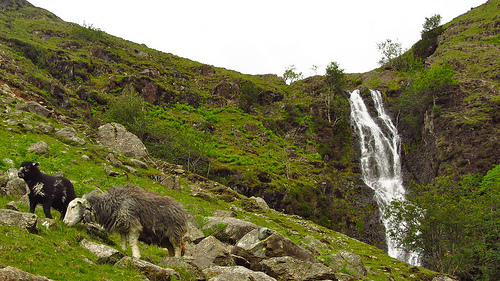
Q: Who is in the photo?
A: No people.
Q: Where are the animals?
A: On the grass.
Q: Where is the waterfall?
A: Right.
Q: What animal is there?
A: Sheep.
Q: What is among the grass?
A: Rocks.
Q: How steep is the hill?
A: Very steep.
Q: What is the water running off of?
A: Cliff.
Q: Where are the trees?
A: Scattered.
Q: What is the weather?
A: Mild.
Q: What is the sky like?
A: Overcast.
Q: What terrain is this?
A: Hillside.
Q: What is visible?
A: Waterfalls.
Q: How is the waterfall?
A: High.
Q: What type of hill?
A: Rocky.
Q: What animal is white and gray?
A: Sheep.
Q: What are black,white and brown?
A: Rocks.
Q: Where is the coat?
A: On sheep.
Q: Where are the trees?
A: On hill.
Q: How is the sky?
A: Overcast.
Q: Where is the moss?
A: On rocks.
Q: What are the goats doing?
A: Walking on the hill.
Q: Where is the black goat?
A: Above the gray goat.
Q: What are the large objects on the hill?
A: Rocks.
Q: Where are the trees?
A: All over the hillside.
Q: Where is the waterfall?
A: To the left of the goats.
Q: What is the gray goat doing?
A: Grazing.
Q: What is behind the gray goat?
A: Rocks.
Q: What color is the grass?
A: Green.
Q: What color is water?
A: White.